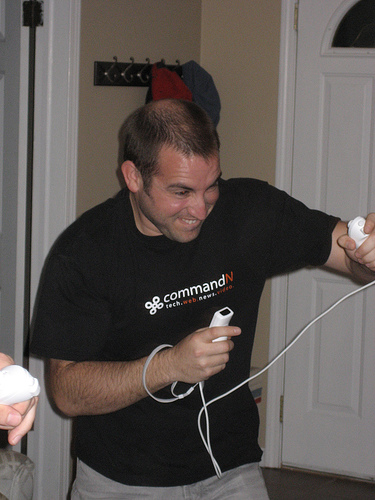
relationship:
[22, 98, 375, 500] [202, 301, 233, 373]
man playing nintendo wii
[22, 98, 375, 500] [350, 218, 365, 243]
man playing on wii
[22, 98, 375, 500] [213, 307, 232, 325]
man playing on wii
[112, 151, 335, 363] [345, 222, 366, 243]
man playing on wii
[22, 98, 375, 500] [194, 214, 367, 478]
man playing on wii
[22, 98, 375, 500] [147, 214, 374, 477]
man playing on nintendo wii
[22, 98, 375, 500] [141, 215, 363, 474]
man playing wii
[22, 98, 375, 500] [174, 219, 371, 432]
man playing wii